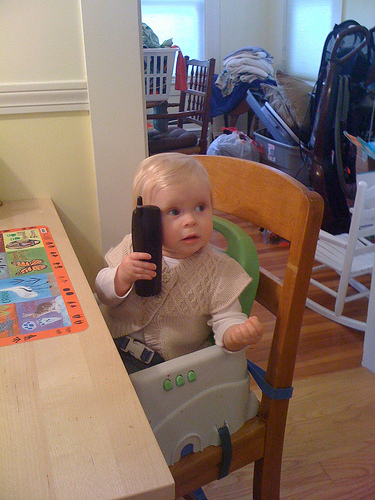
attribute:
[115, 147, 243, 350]
child — blonde, sitting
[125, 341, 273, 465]
seat — booster, baby's, plastic, strapped, green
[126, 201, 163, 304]
phone — black, cordless, wireless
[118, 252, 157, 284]
hand — child's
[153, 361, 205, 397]
buttons — green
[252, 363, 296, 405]
strap — blue, nylon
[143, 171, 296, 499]
chair — wood, rocking, white, high, wooden, brown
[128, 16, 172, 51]
laundry — folded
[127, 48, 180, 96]
basket — white, plastic, laundry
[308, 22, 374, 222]
vacuum — upright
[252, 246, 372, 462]
floor — hardwood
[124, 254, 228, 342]
vest — knitted, tan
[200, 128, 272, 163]
bag — garbage, white, trash, full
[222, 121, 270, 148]
ties — red, plastic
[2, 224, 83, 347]
mat — children's, colorful, plastic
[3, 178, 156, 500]
table — wooden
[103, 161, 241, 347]
toddler — sitting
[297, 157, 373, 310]
chair — white, rocking, small, wooden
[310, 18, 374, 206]
pen — black, mesh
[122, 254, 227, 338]
sweater — beige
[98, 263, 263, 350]
shirt — long sleeved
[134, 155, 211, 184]
hair — blonde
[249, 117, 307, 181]
container — blue, plastic, storage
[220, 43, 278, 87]
clothes — folded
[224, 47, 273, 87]
pile — laundry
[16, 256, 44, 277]
butterfly — monarch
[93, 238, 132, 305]
arm — child's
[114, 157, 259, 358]
baby — sitting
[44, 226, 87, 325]
border — orange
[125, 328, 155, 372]
buckle — white